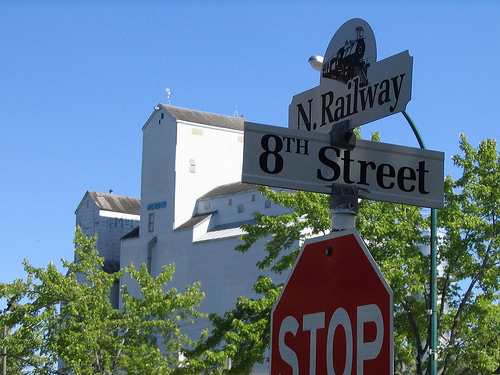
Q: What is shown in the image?
A: Street signs.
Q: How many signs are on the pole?
A: Three.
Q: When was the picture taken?
A: In the daytime.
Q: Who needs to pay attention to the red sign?
A: Cars.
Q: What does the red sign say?
A: Stop.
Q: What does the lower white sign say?
A: 8th street.